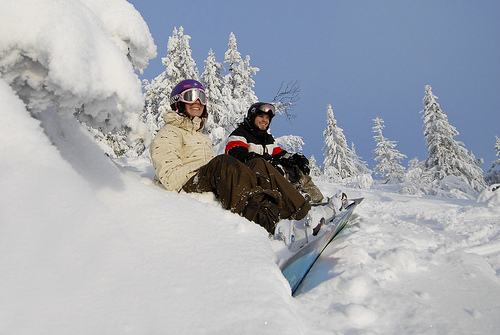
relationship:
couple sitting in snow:
[149, 80, 349, 250] [1, 81, 497, 333]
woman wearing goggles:
[150, 79, 345, 252] [168, 87, 208, 107]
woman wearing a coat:
[150, 79, 345, 252] [150, 111, 217, 192]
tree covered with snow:
[0, 1, 157, 175] [0, 0, 159, 178]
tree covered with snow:
[419, 85, 488, 195] [416, 84, 489, 194]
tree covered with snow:
[320, 105, 375, 187] [322, 101, 375, 187]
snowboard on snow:
[278, 197, 365, 300] [1, 81, 497, 333]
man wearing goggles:
[225, 100, 351, 213] [249, 105, 276, 117]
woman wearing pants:
[150, 79, 345, 252] [182, 152, 312, 235]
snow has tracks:
[1, 81, 497, 333] [321, 194, 496, 333]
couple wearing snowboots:
[149, 80, 349, 250] [274, 189, 346, 252]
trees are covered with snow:
[144, 25, 498, 199] [144, 25, 498, 200]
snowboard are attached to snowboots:
[278, 197, 363, 296] [274, 189, 346, 252]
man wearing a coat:
[225, 100, 351, 213] [225, 118, 299, 162]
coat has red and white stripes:
[225, 118, 299, 162] [223, 135, 285, 156]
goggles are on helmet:
[249, 105, 276, 117] [246, 102, 274, 123]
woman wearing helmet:
[150, 79, 345, 252] [169, 79, 206, 110]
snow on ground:
[1, 81, 497, 333] [1, 160, 494, 334]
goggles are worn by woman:
[168, 87, 208, 107] [150, 79, 345, 252]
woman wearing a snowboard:
[150, 79, 345, 252] [278, 197, 365, 300]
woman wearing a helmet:
[150, 79, 345, 252] [169, 79, 206, 110]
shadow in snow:
[295, 214, 360, 298] [1, 81, 497, 333]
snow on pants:
[191, 171, 312, 232] [182, 152, 312, 235]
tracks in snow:
[321, 194, 496, 333] [1, 81, 497, 333]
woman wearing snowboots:
[150, 79, 345, 252] [274, 203, 338, 255]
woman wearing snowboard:
[150, 79, 345, 252] [278, 197, 365, 300]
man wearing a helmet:
[225, 100, 351, 213] [246, 102, 274, 123]